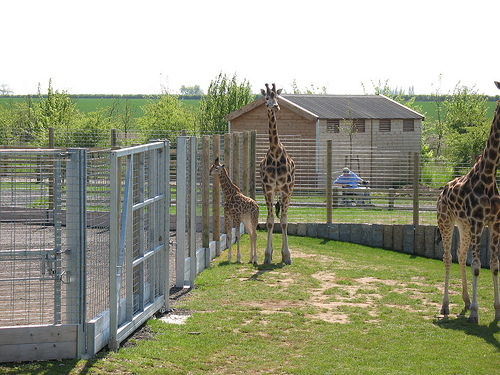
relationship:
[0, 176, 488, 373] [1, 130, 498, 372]
dirt covering inside enclosure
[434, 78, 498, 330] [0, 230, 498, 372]
giraffe standing on grassy area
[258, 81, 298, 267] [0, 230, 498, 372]
adult standing on grassy area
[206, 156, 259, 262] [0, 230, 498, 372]
baby giraffe standing on grassy area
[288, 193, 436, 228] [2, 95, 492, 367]
grass missing in field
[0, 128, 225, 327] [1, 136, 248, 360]
area of enclosure with fence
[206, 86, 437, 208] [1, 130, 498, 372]
building behind enclosure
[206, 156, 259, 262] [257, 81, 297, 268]
baby giraffe standing by giraffe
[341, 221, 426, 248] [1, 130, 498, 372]
stone wall lining enclosure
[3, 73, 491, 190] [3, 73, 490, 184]
trees with leaves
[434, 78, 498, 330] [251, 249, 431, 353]
giraffe standing on grass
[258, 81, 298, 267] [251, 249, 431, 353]
adult standing on grass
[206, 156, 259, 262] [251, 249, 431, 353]
baby giraffe standing on grass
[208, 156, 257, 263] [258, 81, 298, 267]
baby giraffee standing next to adult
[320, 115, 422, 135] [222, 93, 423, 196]
windows on top of building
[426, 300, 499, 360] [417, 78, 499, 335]
shadow from giraffe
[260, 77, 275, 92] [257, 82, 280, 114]
horns on top of head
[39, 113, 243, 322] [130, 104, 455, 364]
fence around enclosure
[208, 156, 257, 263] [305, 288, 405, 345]
baby giraffee standing on grass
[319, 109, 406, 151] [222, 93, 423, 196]
windows on top of building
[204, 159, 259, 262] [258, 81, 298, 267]
baby giraffe standing next to adult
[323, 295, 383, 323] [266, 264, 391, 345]
dirt on ground